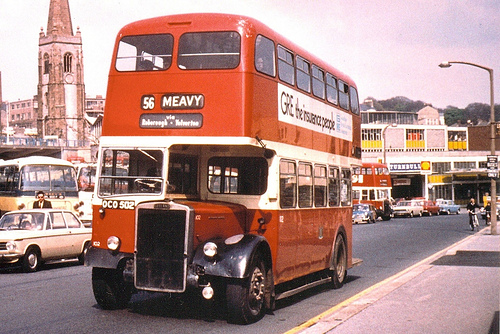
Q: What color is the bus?
A: Red.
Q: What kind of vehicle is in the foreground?
A: A bus.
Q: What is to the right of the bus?
A: The sidewalk.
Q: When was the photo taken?
A: Daytime.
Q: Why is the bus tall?
A: It has two levels.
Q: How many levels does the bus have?
A: Two.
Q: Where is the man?
A: Standing by the car.